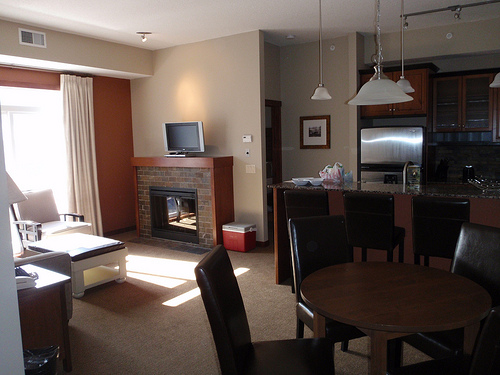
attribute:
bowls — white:
[289, 173, 326, 187]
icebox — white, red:
[220, 220, 258, 252]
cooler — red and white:
[218, 215, 257, 250]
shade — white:
[345, 79, 413, 106]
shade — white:
[397, 78, 416, 93]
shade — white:
[309, 87, 331, 101]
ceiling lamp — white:
[310, 0, 332, 100]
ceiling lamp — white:
[394, 0, 415, 93]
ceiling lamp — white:
[346, 0, 414, 106]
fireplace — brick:
[147, 184, 203, 244]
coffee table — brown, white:
[23, 226, 131, 296]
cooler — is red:
[220, 219, 253, 256]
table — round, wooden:
[294, 255, 496, 374]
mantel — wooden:
[129, 150, 234, 247]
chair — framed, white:
[5, 189, 90, 246]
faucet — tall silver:
[399, 158, 414, 183]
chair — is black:
[201, 275, 270, 370]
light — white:
[310, 0, 332, 101]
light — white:
[395, 1, 415, 93]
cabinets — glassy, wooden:
[426, 59, 499, 139]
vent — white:
[16, 25, 49, 48]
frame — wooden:
[12, 191, 132, 291]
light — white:
[343, 0, 414, 107]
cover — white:
[350, 75, 410, 110]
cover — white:
[307, 85, 336, 104]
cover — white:
[386, 69, 422, 96]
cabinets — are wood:
[427, 69, 484, 138]